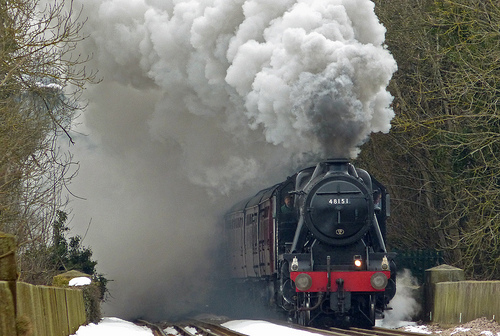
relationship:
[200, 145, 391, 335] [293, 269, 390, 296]
train has headlight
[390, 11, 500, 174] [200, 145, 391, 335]
trees by train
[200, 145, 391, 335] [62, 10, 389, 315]
train has smoke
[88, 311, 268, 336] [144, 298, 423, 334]
snow on tracks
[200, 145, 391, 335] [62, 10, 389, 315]
train blowing smoke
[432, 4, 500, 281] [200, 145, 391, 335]
trees by train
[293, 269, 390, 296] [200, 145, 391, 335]
headlight on train